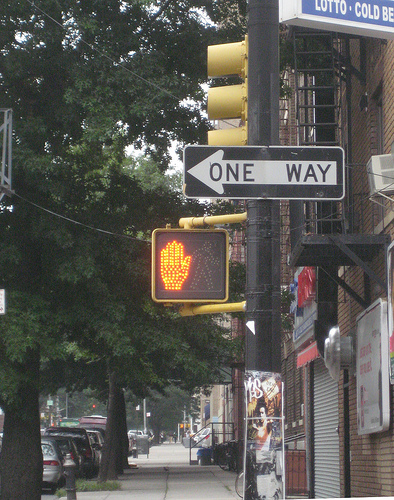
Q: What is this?
A: Street.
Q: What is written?
A: One way.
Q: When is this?
A: Daytime.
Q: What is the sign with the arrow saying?
A: One way.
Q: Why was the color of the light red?
A: To indicate stop.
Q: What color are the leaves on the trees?
A: Green.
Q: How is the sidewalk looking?
A: Empty.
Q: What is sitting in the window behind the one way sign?
A: An air conditioner.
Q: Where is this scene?
A: City.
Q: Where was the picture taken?
A: On the street.